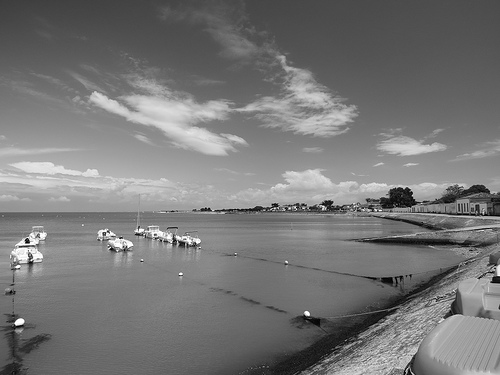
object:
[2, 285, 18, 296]
spot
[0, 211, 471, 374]
seas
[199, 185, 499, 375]
port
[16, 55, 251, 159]
white clouds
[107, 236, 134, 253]
boat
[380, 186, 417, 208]
tree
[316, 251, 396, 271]
spot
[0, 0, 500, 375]
scene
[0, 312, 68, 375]
dark spot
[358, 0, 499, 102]
monochromatic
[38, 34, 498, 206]
weather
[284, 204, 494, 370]
shore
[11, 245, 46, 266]
white boat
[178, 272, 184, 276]
buoey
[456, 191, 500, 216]
white house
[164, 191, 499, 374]
beach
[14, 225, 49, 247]
boats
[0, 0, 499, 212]
cloud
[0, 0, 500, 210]
sky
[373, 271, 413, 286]
spot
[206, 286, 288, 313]
dark spot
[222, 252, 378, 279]
dark spot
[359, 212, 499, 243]
ramp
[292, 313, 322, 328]
spot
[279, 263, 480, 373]
rope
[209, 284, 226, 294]
spot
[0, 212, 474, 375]
water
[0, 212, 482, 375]
bay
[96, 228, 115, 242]
boat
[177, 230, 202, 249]
boat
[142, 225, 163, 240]
boat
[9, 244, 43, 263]
boat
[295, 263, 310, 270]
spot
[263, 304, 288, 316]
spot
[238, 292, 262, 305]
spot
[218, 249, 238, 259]
spot